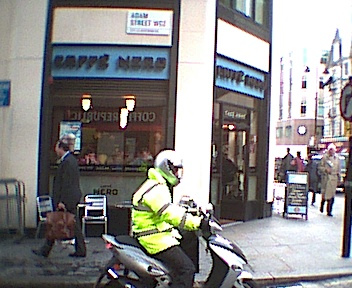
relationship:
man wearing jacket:
[128, 145, 211, 288] [127, 167, 203, 256]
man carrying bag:
[30, 138, 87, 259] [44, 205, 78, 242]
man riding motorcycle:
[128, 145, 211, 288] [93, 195, 257, 287]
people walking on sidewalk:
[281, 144, 343, 217] [220, 178, 352, 280]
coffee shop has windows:
[35, 38, 273, 237] [47, 102, 171, 173]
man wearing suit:
[30, 138, 87, 259] [39, 151, 86, 254]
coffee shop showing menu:
[35, 38, 273, 237] [283, 171, 311, 220]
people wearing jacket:
[281, 147, 293, 187] [282, 154, 294, 169]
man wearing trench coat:
[318, 142, 344, 218] [318, 154, 342, 199]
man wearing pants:
[128, 145, 211, 288] [146, 228, 202, 287]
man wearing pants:
[30, 138, 87, 259] [37, 203, 86, 254]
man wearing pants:
[318, 142, 344, 218] [319, 196, 335, 213]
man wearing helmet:
[128, 145, 211, 288] [154, 149, 186, 187]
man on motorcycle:
[128, 145, 211, 288] [93, 195, 257, 287]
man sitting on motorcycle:
[128, 145, 211, 288] [93, 195, 257, 287]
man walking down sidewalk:
[30, 138, 87, 259] [1, 233, 139, 285]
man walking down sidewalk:
[318, 142, 344, 218] [220, 178, 352, 280]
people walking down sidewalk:
[281, 147, 293, 187] [220, 178, 352, 280]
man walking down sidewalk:
[303, 154, 319, 204] [220, 178, 352, 280]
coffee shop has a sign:
[35, 38, 273, 237] [49, 42, 171, 82]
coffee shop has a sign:
[35, 38, 273, 237] [213, 51, 268, 100]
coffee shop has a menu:
[35, 38, 273, 237] [283, 171, 311, 220]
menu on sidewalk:
[283, 171, 311, 220] [220, 178, 352, 280]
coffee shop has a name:
[35, 38, 273, 237] [53, 54, 166, 71]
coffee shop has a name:
[35, 38, 273, 237] [217, 65, 264, 91]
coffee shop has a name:
[35, 38, 273, 237] [93, 183, 118, 196]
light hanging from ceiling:
[80, 95, 92, 111] [53, 95, 167, 113]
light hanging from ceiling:
[125, 98, 135, 111] [53, 95, 167, 113]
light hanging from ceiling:
[119, 107, 128, 128] [53, 95, 167, 113]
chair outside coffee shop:
[36, 195, 54, 239] [35, 38, 273, 237]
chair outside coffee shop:
[81, 193, 109, 241] [35, 38, 273, 237]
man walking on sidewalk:
[30, 138, 87, 259] [1, 233, 139, 285]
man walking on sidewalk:
[318, 142, 344, 218] [220, 178, 352, 280]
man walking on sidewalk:
[303, 154, 319, 204] [220, 178, 352, 280]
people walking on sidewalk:
[281, 147, 293, 187] [220, 178, 352, 280]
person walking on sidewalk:
[293, 151, 305, 172] [220, 178, 352, 280]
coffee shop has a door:
[35, 38, 273, 237] [218, 117, 250, 222]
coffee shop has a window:
[35, 38, 273, 237] [47, 102, 171, 173]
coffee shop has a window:
[35, 38, 273, 237] [212, 101, 222, 174]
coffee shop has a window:
[35, 38, 273, 237] [249, 110, 257, 167]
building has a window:
[275, 46, 323, 158] [300, 97, 307, 116]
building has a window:
[275, 46, 323, 158] [301, 75, 306, 90]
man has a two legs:
[128, 145, 211, 288] [156, 243, 192, 288]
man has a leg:
[128, 145, 211, 288] [177, 229, 201, 273]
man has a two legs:
[30, 138, 87, 259] [69, 222, 89, 258]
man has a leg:
[30, 138, 87, 259] [32, 232, 56, 256]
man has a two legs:
[318, 142, 344, 218] [326, 200, 334, 218]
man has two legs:
[128, 145, 211, 288] [146, 227, 201, 288]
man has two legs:
[30, 138, 87, 259] [32, 199, 89, 258]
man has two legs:
[318, 142, 344, 218] [319, 195, 334, 218]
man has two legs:
[303, 154, 319, 204] [306, 189, 318, 207]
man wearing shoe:
[30, 138, 87, 259] [70, 250, 87, 258]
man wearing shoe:
[30, 138, 87, 259] [32, 247, 49, 258]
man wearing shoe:
[318, 142, 344, 218] [319, 207, 325, 214]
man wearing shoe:
[318, 142, 344, 218] [328, 212, 333, 217]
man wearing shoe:
[303, 154, 319, 204] [311, 203, 316, 207]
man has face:
[30, 138, 87, 259] [53, 139, 61, 157]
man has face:
[128, 145, 211, 288] [170, 165, 182, 179]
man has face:
[318, 142, 344, 218] [328, 147, 336, 156]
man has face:
[132, 147, 154, 167] [139, 150, 147, 160]